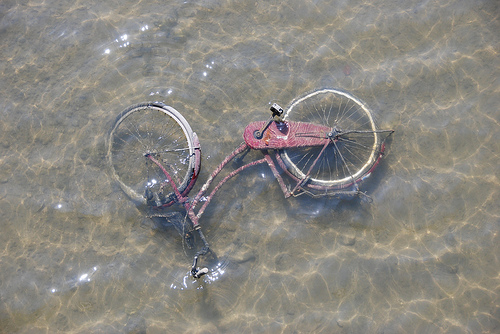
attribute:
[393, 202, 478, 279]
water — shallow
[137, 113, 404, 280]
frame — red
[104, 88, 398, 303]
bike — old, abandoned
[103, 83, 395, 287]
bicycle — rear, wheel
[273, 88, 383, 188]
wheel — helps, fully, submerged, bicycle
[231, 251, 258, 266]
handle — submerged, fully, bicycle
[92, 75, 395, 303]
bike — wheel, red`````````, red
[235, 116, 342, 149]
cover — chain, safety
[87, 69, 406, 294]
bicycle — partially, submerged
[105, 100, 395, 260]
bicycle — laying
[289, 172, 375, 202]
fender — rear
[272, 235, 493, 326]
waves — small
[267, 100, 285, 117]
pedal — bike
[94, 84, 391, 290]
bike — old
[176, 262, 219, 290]
handle — bicycle